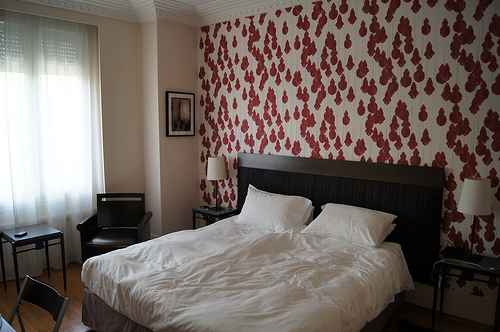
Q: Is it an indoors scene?
A: Yes, it is indoors.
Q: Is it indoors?
A: Yes, it is indoors.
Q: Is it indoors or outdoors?
A: It is indoors.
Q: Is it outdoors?
A: No, it is indoors.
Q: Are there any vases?
A: No, there are no vases.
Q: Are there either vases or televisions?
A: No, there are no vases or televisions.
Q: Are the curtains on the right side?
A: No, the curtains are on the left of the image.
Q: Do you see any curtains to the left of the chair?
A: Yes, there are curtains to the left of the chair.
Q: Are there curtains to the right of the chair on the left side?
A: No, the curtains are to the left of the chair.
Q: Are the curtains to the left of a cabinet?
A: No, the curtains are to the left of the chair.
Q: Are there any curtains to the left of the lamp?
A: Yes, there are curtains to the left of the lamp.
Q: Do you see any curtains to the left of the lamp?
A: Yes, there are curtains to the left of the lamp.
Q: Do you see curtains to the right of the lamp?
A: No, the curtains are to the left of the lamp.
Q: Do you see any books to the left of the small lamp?
A: No, there are curtains to the left of the lamp.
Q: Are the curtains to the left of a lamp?
A: Yes, the curtains are to the left of a lamp.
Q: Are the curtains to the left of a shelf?
A: No, the curtains are to the left of a lamp.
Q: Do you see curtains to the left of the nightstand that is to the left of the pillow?
A: Yes, there are curtains to the left of the nightstand.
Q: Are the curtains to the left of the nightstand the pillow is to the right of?
A: Yes, the curtains are to the left of the nightstand.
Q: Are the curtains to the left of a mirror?
A: No, the curtains are to the left of the nightstand.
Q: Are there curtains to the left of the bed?
A: Yes, there are curtains to the left of the bed.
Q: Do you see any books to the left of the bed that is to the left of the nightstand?
A: No, there are curtains to the left of the bed.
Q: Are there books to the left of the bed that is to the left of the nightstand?
A: No, there are curtains to the left of the bed.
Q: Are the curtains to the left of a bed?
A: Yes, the curtains are to the left of a bed.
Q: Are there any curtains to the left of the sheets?
A: Yes, there are curtains to the left of the sheets.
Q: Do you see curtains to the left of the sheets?
A: Yes, there are curtains to the left of the sheets.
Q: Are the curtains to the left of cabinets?
A: No, the curtains are to the left of the sheets.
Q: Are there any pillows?
A: Yes, there is a pillow.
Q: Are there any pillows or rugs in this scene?
A: Yes, there is a pillow.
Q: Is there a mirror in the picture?
A: No, there are no mirrors.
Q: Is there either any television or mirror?
A: No, there are no mirrors or televisions.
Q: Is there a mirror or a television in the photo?
A: No, there are no mirrors or televisions.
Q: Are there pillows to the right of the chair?
A: Yes, there is a pillow to the right of the chair.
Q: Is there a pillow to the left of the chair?
A: No, the pillow is to the right of the chair.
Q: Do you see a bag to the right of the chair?
A: No, there is a pillow to the right of the chair.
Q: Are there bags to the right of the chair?
A: No, there is a pillow to the right of the chair.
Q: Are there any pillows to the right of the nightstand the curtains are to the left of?
A: Yes, there is a pillow to the right of the nightstand.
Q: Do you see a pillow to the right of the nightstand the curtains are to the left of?
A: Yes, there is a pillow to the right of the nightstand.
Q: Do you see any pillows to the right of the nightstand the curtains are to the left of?
A: Yes, there is a pillow to the right of the nightstand.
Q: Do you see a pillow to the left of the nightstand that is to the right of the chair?
A: No, the pillow is to the right of the nightstand.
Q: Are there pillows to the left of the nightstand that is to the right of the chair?
A: No, the pillow is to the right of the nightstand.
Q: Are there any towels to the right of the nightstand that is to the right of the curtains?
A: No, there is a pillow to the right of the nightstand.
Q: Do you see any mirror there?
A: No, there are no mirrors.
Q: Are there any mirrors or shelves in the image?
A: No, there are no mirrors or shelves.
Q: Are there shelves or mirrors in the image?
A: No, there are no mirrors or shelves.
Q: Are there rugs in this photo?
A: No, there are no rugs.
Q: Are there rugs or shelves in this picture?
A: No, there are no rugs or shelves.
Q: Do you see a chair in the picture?
A: Yes, there is a chair.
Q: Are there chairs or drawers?
A: Yes, there is a chair.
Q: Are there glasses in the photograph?
A: No, there are no glasses.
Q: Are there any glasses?
A: No, there are no glasses.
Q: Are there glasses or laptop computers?
A: No, there are no glasses or laptop computers.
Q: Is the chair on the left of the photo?
A: Yes, the chair is on the left of the image.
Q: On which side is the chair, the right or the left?
A: The chair is on the left of the image.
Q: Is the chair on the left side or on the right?
A: The chair is on the left of the image.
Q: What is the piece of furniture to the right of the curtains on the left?
A: The piece of furniture is a chair.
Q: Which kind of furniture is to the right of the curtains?
A: The piece of furniture is a chair.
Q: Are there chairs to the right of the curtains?
A: Yes, there is a chair to the right of the curtains.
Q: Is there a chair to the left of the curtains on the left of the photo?
A: No, the chair is to the right of the curtains.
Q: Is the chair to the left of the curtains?
A: No, the chair is to the right of the curtains.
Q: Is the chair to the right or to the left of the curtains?
A: The chair is to the right of the curtains.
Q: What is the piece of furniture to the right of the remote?
A: The piece of furniture is a chair.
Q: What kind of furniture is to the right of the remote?
A: The piece of furniture is a chair.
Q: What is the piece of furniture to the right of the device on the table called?
A: The piece of furniture is a chair.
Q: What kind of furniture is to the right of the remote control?
A: The piece of furniture is a chair.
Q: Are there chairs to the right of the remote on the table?
A: Yes, there is a chair to the right of the remote control.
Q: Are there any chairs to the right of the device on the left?
A: Yes, there is a chair to the right of the remote control.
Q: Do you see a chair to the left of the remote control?
A: No, the chair is to the right of the remote control.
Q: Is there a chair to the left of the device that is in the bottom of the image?
A: No, the chair is to the right of the remote control.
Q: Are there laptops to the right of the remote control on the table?
A: No, there is a chair to the right of the remote.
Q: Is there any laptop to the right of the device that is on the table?
A: No, there is a chair to the right of the remote.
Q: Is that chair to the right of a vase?
A: No, the chair is to the right of a remote control.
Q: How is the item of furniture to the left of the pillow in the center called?
A: The piece of furniture is a chair.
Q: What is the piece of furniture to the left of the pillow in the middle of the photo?
A: The piece of furniture is a chair.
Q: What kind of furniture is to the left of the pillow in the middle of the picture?
A: The piece of furniture is a chair.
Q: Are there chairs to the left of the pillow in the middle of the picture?
A: Yes, there is a chair to the left of the pillow.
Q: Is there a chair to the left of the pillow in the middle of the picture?
A: Yes, there is a chair to the left of the pillow.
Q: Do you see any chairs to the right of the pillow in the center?
A: No, the chair is to the left of the pillow.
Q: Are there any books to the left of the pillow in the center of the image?
A: No, there is a chair to the left of the pillow.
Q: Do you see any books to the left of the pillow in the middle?
A: No, there is a chair to the left of the pillow.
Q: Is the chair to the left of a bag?
A: No, the chair is to the left of the pillow.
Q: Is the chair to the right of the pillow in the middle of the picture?
A: No, the chair is to the left of the pillow.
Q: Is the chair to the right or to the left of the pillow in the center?
A: The chair is to the left of the pillow.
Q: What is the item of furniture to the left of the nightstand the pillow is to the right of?
A: The piece of furniture is a chair.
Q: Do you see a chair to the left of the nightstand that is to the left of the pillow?
A: Yes, there is a chair to the left of the nightstand.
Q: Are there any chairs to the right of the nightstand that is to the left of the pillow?
A: No, the chair is to the left of the nightstand.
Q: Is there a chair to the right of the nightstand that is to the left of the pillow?
A: No, the chair is to the left of the nightstand.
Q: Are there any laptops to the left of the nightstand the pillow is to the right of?
A: No, there is a chair to the left of the nightstand.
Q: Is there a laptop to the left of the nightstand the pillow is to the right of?
A: No, there is a chair to the left of the nightstand.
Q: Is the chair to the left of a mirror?
A: No, the chair is to the left of the nightstand.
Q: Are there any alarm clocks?
A: No, there are no alarm clocks.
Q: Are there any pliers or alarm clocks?
A: No, there are no alarm clocks or pliers.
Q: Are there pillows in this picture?
A: Yes, there is a pillow.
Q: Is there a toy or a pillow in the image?
A: Yes, there is a pillow.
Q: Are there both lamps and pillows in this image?
A: Yes, there are both a pillow and a lamp.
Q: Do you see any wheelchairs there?
A: No, there are no wheelchairs.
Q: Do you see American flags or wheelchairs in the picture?
A: No, there are no wheelchairs or American flags.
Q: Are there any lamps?
A: Yes, there is a lamp.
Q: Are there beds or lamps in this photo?
A: Yes, there is a lamp.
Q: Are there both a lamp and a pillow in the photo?
A: Yes, there are both a lamp and a pillow.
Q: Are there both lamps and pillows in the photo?
A: Yes, there are both a lamp and pillows.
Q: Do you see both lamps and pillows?
A: Yes, there are both a lamp and pillows.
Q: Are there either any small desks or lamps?
A: Yes, there is a small lamp.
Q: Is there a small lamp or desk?
A: Yes, there is a small lamp.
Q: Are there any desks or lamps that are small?
A: Yes, the lamp is small.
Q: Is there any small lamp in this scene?
A: Yes, there is a small lamp.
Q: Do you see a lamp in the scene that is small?
A: Yes, there is a lamp that is small.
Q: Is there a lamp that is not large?
A: Yes, there is a small lamp.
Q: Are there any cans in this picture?
A: No, there are no cans.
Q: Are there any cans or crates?
A: No, there are no cans or crates.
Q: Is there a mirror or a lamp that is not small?
A: No, there is a lamp but it is small.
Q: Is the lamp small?
A: Yes, the lamp is small.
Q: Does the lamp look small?
A: Yes, the lamp is small.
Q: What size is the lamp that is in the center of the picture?
A: The lamp is small.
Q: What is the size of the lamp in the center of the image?
A: The lamp is small.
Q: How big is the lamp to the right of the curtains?
A: The lamp is small.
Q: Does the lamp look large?
A: No, the lamp is small.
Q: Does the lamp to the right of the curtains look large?
A: No, the lamp is small.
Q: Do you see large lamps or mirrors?
A: No, there is a lamp but it is small.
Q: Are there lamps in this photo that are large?
A: No, there is a lamp but it is small.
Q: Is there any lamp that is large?
A: No, there is a lamp but it is small.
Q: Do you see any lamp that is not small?
A: No, there is a lamp but it is small.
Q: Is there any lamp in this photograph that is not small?
A: No, there is a lamp but it is small.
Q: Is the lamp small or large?
A: The lamp is small.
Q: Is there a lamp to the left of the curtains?
A: No, the lamp is to the right of the curtains.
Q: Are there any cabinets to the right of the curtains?
A: No, there is a lamp to the right of the curtains.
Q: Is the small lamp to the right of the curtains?
A: Yes, the lamp is to the right of the curtains.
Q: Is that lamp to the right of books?
A: No, the lamp is to the right of the curtains.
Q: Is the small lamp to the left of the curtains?
A: No, the lamp is to the right of the curtains.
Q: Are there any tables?
A: Yes, there is a table.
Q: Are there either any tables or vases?
A: Yes, there is a table.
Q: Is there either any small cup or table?
A: Yes, there is a small table.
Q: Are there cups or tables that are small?
A: Yes, the table is small.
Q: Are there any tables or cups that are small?
A: Yes, the table is small.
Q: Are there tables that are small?
A: Yes, there is a small table.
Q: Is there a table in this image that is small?
A: Yes, there is a table that is small.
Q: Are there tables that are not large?
A: Yes, there is a small table.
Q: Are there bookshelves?
A: No, there are no bookshelves.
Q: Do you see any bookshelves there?
A: No, there are no bookshelves.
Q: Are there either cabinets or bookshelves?
A: No, there are no bookshelves or cabinets.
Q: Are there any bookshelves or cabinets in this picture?
A: No, there are no bookshelves or cabinets.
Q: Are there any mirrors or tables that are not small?
A: No, there is a table but it is small.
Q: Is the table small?
A: Yes, the table is small.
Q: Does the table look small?
A: Yes, the table is small.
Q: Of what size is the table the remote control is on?
A: The table is small.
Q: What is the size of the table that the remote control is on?
A: The table is small.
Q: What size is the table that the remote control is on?
A: The table is small.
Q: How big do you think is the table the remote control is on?
A: The table is small.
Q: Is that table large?
A: No, the table is small.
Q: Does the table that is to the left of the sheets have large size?
A: No, the table is small.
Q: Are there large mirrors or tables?
A: No, there is a table but it is small.